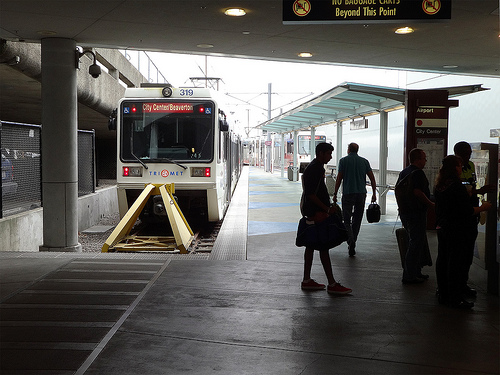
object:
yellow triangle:
[100, 184, 194, 254]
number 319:
[179, 89, 193, 97]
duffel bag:
[292, 202, 358, 251]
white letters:
[413, 106, 441, 112]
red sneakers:
[300, 282, 325, 291]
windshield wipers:
[129, 122, 148, 170]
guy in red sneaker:
[296, 144, 351, 301]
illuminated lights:
[223, 4, 248, 17]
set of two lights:
[122, 165, 211, 182]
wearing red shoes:
[300, 278, 353, 296]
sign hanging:
[349, 120, 367, 130]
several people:
[295, 142, 498, 300]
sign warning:
[287, 0, 446, 23]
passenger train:
[103, 81, 256, 234]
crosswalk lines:
[3, 249, 176, 375]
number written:
[148, 169, 184, 177]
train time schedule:
[412, 140, 444, 207]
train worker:
[444, 141, 477, 296]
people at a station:
[435, 141, 480, 310]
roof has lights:
[8, 0, 500, 78]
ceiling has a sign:
[276, 0, 457, 25]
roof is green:
[253, 81, 406, 136]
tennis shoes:
[326, 284, 352, 297]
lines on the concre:
[248, 128, 403, 236]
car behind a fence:
[239, 130, 329, 167]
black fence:
[300, 169, 424, 187]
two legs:
[301, 293, 344, 321]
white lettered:
[140, 103, 197, 111]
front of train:
[117, 87, 213, 181]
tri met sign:
[147, 171, 183, 176]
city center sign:
[413, 118, 448, 159]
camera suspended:
[88, 64, 101, 80]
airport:
[402, 108, 449, 135]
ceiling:
[0, 0, 500, 75]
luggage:
[292, 201, 353, 253]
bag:
[362, 194, 385, 226]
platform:
[232, 164, 499, 373]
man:
[394, 148, 434, 286]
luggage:
[369, 202, 382, 224]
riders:
[484, 131, 500, 301]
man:
[333, 143, 381, 259]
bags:
[306, 208, 345, 248]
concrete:
[0, 253, 500, 375]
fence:
[244, 131, 301, 186]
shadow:
[290, 293, 368, 375]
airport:
[1, 116, 498, 375]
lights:
[112, 161, 137, 177]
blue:
[147, 171, 184, 176]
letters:
[144, 94, 196, 114]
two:
[426, 140, 486, 311]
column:
[41, 49, 79, 254]